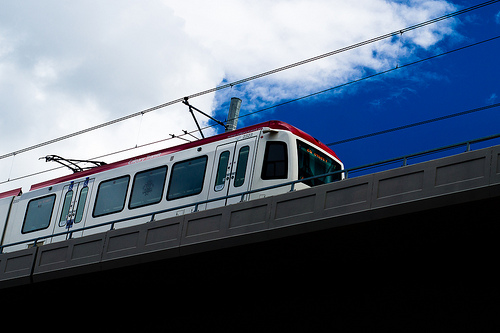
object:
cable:
[0, 0, 500, 184]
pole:
[224, 97, 242, 133]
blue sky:
[209, 0, 499, 179]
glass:
[296, 138, 342, 188]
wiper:
[306, 152, 314, 181]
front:
[280, 120, 346, 195]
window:
[292, 140, 344, 188]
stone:
[2, 147, 500, 287]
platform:
[1, 134, 500, 287]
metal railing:
[0, 134, 500, 248]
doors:
[205, 136, 257, 209]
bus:
[1, 119, 346, 256]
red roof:
[118, 117, 309, 144]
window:
[167, 156, 206, 198]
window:
[94, 175, 127, 215]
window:
[22, 194, 53, 231]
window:
[74, 183, 86, 225]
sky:
[2, 1, 498, 192]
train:
[2, 120, 346, 253]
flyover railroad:
[0, 133, 500, 333]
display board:
[299, 143, 331, 167]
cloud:
[0, 0, 459, 192]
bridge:
[0, 134, 500, 289]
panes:
[90, 153, 206, 218]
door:
[50, 177, 93, 242]